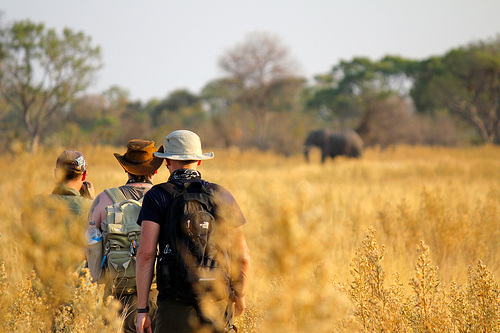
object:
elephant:
[302, 127, 364, 163]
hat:
[154, 130, 214, 161]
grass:
[296, 166, 485, 313]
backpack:
[155, 182, 230, 302]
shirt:
[136, 167, 247, 302]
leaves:
[451, 59, 494, 81]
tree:
[221, 37, 313, 91]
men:
[84, 138, 164, 332]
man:
[136, 129, 248, 331]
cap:
[113, 138, 163, 175]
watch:
[135, 305, 150, 312]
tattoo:
[87, 193, 101, 218]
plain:
[5, 143, 484, 332]